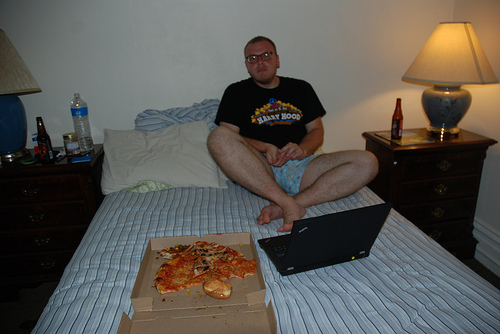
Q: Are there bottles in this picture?
A: Yes, there is a bottle.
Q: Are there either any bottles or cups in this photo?
A: Yes, there is a bottle.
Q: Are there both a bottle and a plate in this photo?
A: No, there is a bottle but no plates.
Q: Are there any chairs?
A: No, there are no chairs.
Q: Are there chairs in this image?
A: No, there are no chairs.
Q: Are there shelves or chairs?
A: No, there are no chairs or shelves.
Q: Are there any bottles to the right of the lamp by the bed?
A: No, the bottle is to the left of the lamp.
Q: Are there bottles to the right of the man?
A: Yes, there is a bottle to the right of the man.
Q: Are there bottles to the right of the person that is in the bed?
A: Yes, there is a bottle to the right of the man.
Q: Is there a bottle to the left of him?
A: No, the bottle is to the right of the man.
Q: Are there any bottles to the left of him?
A: No, the bottle is to the right of the man.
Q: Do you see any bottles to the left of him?
A: No, the bottle is to the right of the man.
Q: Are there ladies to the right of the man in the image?
A: No, there is a bottle to the right of the man.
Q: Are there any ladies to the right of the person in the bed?
A: No, there is a bottle to the right of the man.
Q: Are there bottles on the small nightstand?
A: Yes, there is a bottle on the nightstand.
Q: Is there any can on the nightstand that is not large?
A: No, there is a bottle on the nightstand.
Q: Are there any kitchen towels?
A: No, there are no kitchen towels.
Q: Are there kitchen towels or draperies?
A: No, there are no kitchen towels or draperies.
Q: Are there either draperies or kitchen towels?
A: No, there are no kitchen towels or draperies.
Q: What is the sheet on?
A: The sheet is on the bed.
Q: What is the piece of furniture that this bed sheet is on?
A: The piece of furniture is a bed.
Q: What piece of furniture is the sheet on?
A: The bed sheet is on the bed.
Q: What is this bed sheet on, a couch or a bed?
A: The bed sheet is on a bed.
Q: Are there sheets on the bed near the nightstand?
A: Yes, there is a sheet on the bed.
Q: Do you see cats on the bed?
A: No, there is a sheet on the bed.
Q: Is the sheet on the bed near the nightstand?
A: Yes, the sheet is on the bed.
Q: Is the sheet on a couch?
A: No, the sheet is on the bed.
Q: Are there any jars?
A: No, there are no jars.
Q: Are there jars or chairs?
A: No, there are no jars or chairs.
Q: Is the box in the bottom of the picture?
A: Yes, the box is in the bottom of the image.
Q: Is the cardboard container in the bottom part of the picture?
A: Yes, the box is in the bottom of the image.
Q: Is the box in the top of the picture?
A: No, the box is in the bottom of the image.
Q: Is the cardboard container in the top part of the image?
A: No, the box is in the bottom of the image.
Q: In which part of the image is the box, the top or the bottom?
A: The box is in the bottom of the image.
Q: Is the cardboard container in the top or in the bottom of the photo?
A: The box is in the bottom of the image.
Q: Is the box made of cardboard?
A: Yes, the box is made of cardboard.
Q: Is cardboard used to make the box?
A: Yes, the box is made of cardboard.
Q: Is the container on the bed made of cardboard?
A: Yes, the box is made of cardboard.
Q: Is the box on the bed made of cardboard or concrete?
A: The box is made of cardboard.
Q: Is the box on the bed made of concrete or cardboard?
A: The box is made of cardboard.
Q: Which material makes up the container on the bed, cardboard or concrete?
A: The box is made of cardboard.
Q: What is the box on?
A: The box is on the bed.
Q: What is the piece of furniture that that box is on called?
A: The piece of furniture is a bed.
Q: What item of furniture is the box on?
A: The box is on the bed.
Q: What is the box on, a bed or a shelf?
A: The box is on a bed.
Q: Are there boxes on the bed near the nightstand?
A: Yes, there is a box on the bed.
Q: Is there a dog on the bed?
A: No, there is a box on the bed.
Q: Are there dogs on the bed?
A: No, there is a box on the bed.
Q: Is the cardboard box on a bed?
A: Yes, the box is on a bed.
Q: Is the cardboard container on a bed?
A: Yes, the box is on a bed.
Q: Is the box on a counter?
A: No, the box is on a bed.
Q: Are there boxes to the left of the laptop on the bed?
A: Yes, there is a box to the left of the laptop.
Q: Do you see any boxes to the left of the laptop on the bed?
A: Yes, there is a box to the left of the laptop.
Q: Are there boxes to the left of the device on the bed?
A: Yes, there is a box to the left of the laptop.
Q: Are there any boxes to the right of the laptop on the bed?
A: No, the box is to the left of the laptop.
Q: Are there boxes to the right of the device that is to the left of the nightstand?
A: No, the box is to the left of the laptop.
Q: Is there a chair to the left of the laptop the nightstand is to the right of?
A: No, there is a box to the left of the laptop.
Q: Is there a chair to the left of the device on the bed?
A: No, there is a box to the left of the laptop.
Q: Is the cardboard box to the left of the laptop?
A: Yes, the box is to the left of the laptop.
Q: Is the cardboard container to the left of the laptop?
A: Yes, the box is to the left of the laptop.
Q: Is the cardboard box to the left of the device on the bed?
A: Yes, the box is to the left of the laptop.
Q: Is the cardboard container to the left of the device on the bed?
A: Yes, the box is to the left of the laptop.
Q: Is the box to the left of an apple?
A: No, the box is to the left of the laptop.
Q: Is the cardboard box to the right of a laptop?
A: No, the box is to the left of a laptop.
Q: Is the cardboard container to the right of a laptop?
A: No, the box is to the left of a laptop.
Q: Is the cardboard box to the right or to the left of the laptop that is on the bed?
A: The box is to the left of the laptop computer.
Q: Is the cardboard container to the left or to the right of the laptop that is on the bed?
A: The box is to the left of the laptop computer.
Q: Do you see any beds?
A: Yes, there is a bed.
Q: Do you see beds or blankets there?
A: Yes, there is a bed.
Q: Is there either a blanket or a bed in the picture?
A: Yes, there is a bed.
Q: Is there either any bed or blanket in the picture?
A: Yes, there is a bed.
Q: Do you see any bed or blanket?
A: Yes, there is a bed.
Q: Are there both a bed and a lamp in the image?
A: Yes, there are both a bed and a lamp.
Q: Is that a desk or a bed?
A: That is a bed.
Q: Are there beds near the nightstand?
A: Yes, there is a bed near the nightstand.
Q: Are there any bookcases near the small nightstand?
A: No, there is a bed near the nightstand.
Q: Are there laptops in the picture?
A: Yes, there is a laptop.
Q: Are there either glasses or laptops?
A: Yes, there is a laptop.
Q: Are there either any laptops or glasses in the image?
A: Yes, there is a laptop.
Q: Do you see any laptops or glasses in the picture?
A: Yes, there is a laptop.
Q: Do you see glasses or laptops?
A: Yes, there is a laptop.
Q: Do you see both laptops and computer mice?
A: No, there is a laptop but no computer mice.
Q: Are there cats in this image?
A: No, there are no cats.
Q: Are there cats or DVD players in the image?
A: No, there are no cats or DVD players.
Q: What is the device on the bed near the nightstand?
A: The device is a laptop.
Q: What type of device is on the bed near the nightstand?
A: The device is a laptop.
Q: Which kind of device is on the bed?
A: The device is a laptop.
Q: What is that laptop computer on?
A: The laptop computer is on the bed.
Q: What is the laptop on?
A: The laptop computer is on the bed.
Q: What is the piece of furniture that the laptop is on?
A: The piece of furniture is a bed.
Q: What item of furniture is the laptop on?
A: The laptop is on the bed.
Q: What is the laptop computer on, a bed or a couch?
A: The laptop computer is on a bed.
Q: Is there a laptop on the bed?
A: Yes, there is a laptop on the bed.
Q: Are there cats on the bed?
A: No, there is a laptop on the bed.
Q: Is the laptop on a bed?
A: Yes, the laptop is on a bed.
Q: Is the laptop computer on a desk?
A: No, the laptop computer is on a bed.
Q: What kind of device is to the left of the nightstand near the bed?
A: The device is a laptop.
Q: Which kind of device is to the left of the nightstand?
A: The device is a laptop.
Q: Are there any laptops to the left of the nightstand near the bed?
A: Yes, there is a laptop to the left of the nightstand.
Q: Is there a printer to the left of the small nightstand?
A: No, there is a laptop to the left of the nightstand.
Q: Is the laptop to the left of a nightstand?
A: Yes, the laptop is to the left of a nightstand.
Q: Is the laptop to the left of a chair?
A: No, the laptop is to the left of a nightstand.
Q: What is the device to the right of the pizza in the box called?
A: The device is a laptop.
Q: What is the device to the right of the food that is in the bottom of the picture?
A: The device is a laptop.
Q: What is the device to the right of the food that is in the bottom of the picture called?
A: The device is a laptop.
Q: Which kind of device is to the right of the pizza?
A: The device is a laptop.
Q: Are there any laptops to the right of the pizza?
A: Yes, there is a laptop to the right of the pizza.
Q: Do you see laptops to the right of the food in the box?
A: Yes, there is a laptop to the right of the pizza.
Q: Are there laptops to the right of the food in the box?
A: Yes, there is a laptop to the right of the pizza.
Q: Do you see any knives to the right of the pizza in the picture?
A: No, there is a laptop to the right of the pizza.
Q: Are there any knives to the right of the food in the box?
A: No, there is a laptop to the right of the pizza.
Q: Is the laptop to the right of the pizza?
A: Yes, the laptop is to the right of the pizza.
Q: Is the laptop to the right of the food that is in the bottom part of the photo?
A: Yes, the laptop is to the right of the pizza.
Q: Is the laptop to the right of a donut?
A: No, the laptop is to the right of the pizza.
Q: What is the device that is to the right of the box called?
A: The device is a laptop.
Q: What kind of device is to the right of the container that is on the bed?
A: The device is a laptop.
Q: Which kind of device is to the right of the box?
A: The device is a laptop.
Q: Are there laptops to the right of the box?
A: Yes, there is a laptop to the right of the box.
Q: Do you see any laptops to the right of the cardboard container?
A: Yes, there is a laptop to the right of the box.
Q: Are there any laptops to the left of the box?
A: No, the laptop is to the right of the box.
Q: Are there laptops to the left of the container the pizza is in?
A: No, the laptop is to the right of the box.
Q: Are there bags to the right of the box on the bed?
A: No, there is a laptop to the right of the box.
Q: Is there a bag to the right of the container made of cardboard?
A: No, there is a laptop to the right of the box.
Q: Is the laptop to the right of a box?
A: Yes, the laptop is to the right of a box.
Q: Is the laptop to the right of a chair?
A: No, the laptop is to the right of a box.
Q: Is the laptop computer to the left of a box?
A: No, the laptop computer is to the right of a box.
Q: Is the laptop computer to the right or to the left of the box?
A: The laptop computer is to the right of the box.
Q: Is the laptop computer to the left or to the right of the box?
A: The laptop computer is to the right of the box.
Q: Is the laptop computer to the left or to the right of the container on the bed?
A: The laptop computer is to the right of the box.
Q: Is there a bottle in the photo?
A: Yes, there is a bottle.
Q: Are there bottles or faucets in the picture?
A: Yes, there is a bottle.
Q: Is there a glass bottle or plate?
A: Yes, there is a glass bottle.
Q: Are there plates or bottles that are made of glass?
A: Yes, the bottle is made of glass.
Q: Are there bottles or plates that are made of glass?
A: Yes, the bottle is made of glass.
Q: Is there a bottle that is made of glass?
A: Yes, there is a bottle that is made of glass.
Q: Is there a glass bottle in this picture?
A: Yes, there is a bottle that is made of glass.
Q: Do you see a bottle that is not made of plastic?
A: Yes, there is a bottle that is made of glass.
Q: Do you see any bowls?
A: No, there are no bowls.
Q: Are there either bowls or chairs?
A: No, there are no bowls or chairs.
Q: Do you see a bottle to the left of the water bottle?
A: Yes, there is a bottle to the left of the water bottle.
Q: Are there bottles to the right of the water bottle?
A: No, the bottle is to the left of the water bottle.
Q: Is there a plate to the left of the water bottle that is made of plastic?
A: No, there is a bottle to the left of the water bottle.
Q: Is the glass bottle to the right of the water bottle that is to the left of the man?
A: No, the bottle is to the left of the water bottle.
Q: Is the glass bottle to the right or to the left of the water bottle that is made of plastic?
A: The bottle is to the left of the water bottle.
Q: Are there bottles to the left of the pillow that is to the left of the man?
A: Yes, there is a bottle to the left of the pillow.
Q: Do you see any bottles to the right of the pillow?
A: No, the bottle is to the left of the pillow.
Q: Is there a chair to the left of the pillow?
A: No, there is a bottle to the left of the pillow.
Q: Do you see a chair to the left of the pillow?
A: No, there is a bottle to the left of the pillow.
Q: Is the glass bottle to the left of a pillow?
A: Yes, the bottle is to the left of a pillow.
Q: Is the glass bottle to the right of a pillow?
A: No, the bottle is to the left of a pillow.